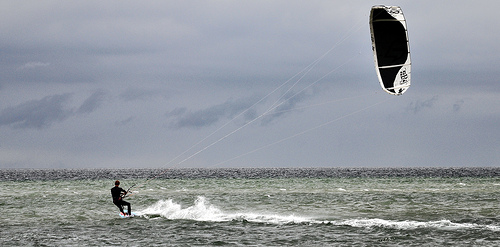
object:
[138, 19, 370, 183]
strings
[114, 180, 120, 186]
head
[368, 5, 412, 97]
kite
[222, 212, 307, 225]
wave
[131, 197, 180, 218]
wave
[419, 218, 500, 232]
wave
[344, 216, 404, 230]
wave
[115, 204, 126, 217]
leg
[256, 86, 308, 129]
cloudy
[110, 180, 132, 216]
man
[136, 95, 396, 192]
rope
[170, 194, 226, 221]
waves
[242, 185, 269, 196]
wave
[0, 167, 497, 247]
water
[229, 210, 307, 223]
wave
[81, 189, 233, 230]
water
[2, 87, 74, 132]
cloud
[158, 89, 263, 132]
cloud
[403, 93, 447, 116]
cloud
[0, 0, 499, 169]
air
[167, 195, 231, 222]
splash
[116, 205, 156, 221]
surfing